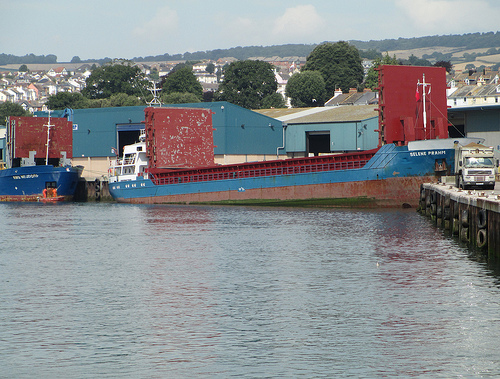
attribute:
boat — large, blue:
[1, 105, 83, 202]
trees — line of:
[3, 32, 498, 62]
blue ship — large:
[124, 140, 424, 215]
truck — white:
[452, 138, 496, 190]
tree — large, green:
[298, 37, 362, 92]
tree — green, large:
[286, 69, 328, 108]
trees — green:
[290, 77, 327, 105]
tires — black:
[414, 184, 490, 251]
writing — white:
[403, 140, 459, 165]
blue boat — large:
[2, 159, 73, 203]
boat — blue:
[109, 132, 460, 203]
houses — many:
[1, 68, 89, 107]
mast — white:
[412, 72, 437, 139]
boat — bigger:
[101, 60, 481, 211]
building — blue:
[10, 96, 377, 176]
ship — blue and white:
[105, 61, 483, 203]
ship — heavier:
[110, 54, 482, 223]